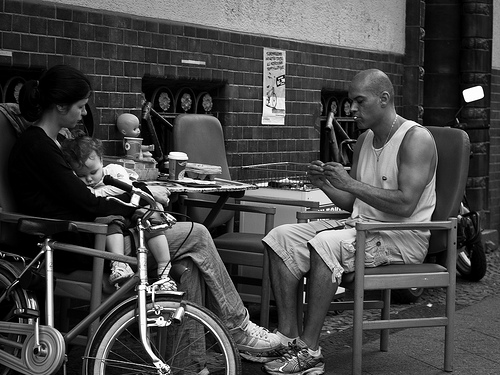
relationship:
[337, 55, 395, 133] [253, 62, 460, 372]
head of man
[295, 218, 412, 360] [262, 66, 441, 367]
leg of man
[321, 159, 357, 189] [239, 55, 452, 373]
hand of man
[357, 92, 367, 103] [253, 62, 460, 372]
eye of man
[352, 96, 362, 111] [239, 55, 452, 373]
nose of man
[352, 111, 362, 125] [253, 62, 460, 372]
mouth of man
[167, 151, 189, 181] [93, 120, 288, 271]
cup on table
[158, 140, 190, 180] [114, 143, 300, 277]
cup on table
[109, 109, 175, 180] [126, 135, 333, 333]
babydoll on table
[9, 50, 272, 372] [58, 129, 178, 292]
woman holding baby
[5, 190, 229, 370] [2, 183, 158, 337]
bike parked nest